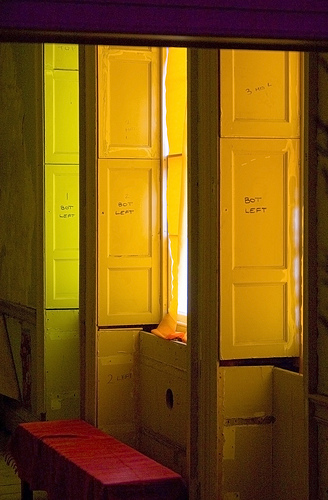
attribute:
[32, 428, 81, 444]
cloth — red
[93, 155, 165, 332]
cabinet panel — white , wood 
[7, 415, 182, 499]
blanket — red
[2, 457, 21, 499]
floor — wooden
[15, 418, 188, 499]
bench — red, sits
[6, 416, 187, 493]
blanket — red, fringed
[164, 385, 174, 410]
hole — round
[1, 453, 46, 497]
floor — wooden planks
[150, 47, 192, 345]
curtain — closed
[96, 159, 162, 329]
shutter — white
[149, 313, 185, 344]
material — red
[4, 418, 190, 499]
table — red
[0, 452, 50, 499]
boards — wooded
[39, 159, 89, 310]
cabinet — white , wood 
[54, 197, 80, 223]
word — marker, black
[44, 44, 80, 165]
cabinet — wood , white 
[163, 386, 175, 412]
hole — circular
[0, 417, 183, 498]
cloth — red